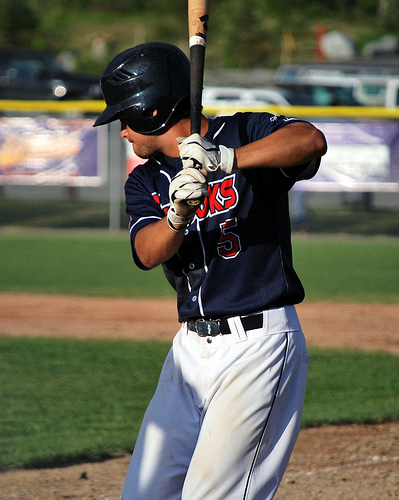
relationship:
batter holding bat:
[82, 27, 334, 496] [179, 0, 213, 211]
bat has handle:
[179, 0, 213, 211] [183, 46, 210, 178]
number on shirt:
[213, 212, 253, 261] [104, 108, 340, 311]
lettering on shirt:
[145, 176, 268, 273] [104, 108, 340, 311]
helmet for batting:
[74, 34, 221, 131] [83, 10, 352, 278]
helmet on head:
[74, 34, 221, 131] [95, 38, 230, 171]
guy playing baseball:
[82, 27, 334, 496] [52, 2, 388, 416]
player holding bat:
[82, 27, 334, 496] [179, 0, 213, 211]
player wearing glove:
[82, 27, 334, 496] [166, 171, 208, 226]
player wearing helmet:
[82, 27, 334, 496] [74, 34, 221, 131]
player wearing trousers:
[82, 27, 334, 496] [120, 298, 313, 499]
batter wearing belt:
[82, 27, 334, 496] [168, 312, 302, 340]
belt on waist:
[168, 312, 302, 340] [171, 290, 313, 364]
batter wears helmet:
[82, 27, 334, 496] [74, 34, 221, 131]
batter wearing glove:
[82, 27, 334, 496] [166, 171, 208, 226]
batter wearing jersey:
[82, 27, 334, 496] [104, 108, 340, 311]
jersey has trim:
[104, 108, 340, 311] [125, 153, 317, 316]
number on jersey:
[213, 212, 253, 261] [104, 108, 340, 311]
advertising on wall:
[2, 113, 397, 190] [2, 100, 392, 230]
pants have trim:
[120, 298, 313, 499] [243, 332, 300, 498]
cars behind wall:
[1, 45, 396, 111] [2, 100, 392, 230]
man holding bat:
[82, 27, 334, 496] [179, 0, 213, 211]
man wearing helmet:
[82, 27, 334, 496] [74, 34, 221, 131]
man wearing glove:
[82, 27, 334, 496] [166, 171, 208, 226]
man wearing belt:
[82, 27, 334, 496] [168, 312, 302, 340]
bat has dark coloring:
[179, 0, 213, 211] [183, 46, 210, 178]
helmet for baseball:
[74, 34, 221, 131] [52, 2, 388, 416]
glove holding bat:
[166, 171, 208, 226] [179, 0, 213, 211]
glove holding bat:
[166, 171, 215, 230] [179, 0, 213, 211]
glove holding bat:
[174, 135, 246, 174] [179, 0, 213, 211]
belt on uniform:
[168, 312, 302, 340] [111, 111, 306, 496]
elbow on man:
[269, 117, 336, 169] [82, 27, 334, 496]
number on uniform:
[213, 212, 253, 261] [111, 111, 306, 496]